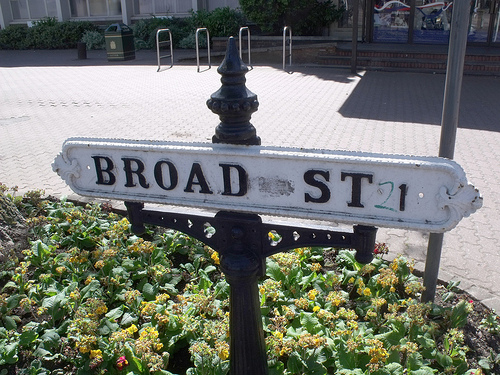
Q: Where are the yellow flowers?
A: Around sign.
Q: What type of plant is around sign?
A: Flowers.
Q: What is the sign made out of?
A: Metal.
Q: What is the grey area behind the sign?
A: Sidewalk.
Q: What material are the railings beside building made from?
A: Metal.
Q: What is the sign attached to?
A: Black pole.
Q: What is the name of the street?
A: Broad.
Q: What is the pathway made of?
A: Brick.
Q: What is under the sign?
A: Flowers.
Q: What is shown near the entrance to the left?
A: Trash can.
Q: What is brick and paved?
A: Driveway.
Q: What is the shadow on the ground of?
A: Building.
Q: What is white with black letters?
A: Sign.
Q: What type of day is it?
A: Sunny.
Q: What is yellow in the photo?
A: Flowers.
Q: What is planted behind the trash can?
A: Shrubs.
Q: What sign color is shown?
A: White and black.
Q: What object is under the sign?
A: Flowers.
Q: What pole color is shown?
A: Black.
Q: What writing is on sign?
A: BROAD ST.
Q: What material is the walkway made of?
A: Brick.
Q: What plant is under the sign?
A: Cactus.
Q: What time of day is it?
A: Daytime.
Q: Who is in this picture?
A: No one.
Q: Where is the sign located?
A: Pole.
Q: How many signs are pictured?
A: One.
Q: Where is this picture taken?
A: Street.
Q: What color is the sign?
A: White.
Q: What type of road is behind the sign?
A: Stone.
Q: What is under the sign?
A: Plants.